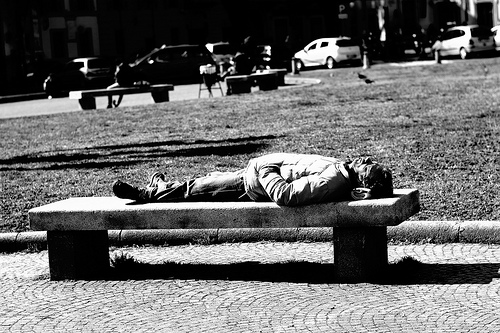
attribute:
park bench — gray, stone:
[24, 185, 421, 281]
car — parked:
[427, 23, 495, 59]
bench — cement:
[24, 189, 437, 274]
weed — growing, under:
[106, 253, 148, 295]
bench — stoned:
[21, 187, 436, 297]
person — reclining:
[118, 137, 400, 222]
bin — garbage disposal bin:
[194, 61, 234, 102]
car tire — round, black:
[291, 59, 307, 71]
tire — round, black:
[460, 48, 467, 58]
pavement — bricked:
[18, 290, 491, 325]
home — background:
[374, 6, 461, 46]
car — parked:
[284, 30, 345, 68]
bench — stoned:
[27, 190, 422, 280]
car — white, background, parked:
[289, 34, 360, 74]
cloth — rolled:
[351, 184, 373, 201]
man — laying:
[111, 151, 390, 208]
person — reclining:
[110, 154, 393, 209]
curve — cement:
[1, 218, 498, 251]